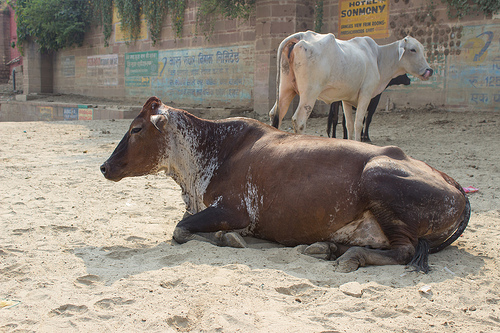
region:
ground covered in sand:
[221, 297, 277, 331]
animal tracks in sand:
[24, 247, 181, 330]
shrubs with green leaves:
[7, 2, 91, 57]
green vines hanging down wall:
[92, 2, 255, 45]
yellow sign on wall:
[333, 0, 400, 40]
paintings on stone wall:
[53, 41, 255, 107]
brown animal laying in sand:
[80, 90, 461, 292]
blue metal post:
[7, 66, 21, 97]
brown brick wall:
[257, 7, 299, 32]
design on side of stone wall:
[464, 23, 498, 70]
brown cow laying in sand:
[100, 98, 473, 292]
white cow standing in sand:
[268, 28, 434, 141]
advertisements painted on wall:
[53, 51, 258, 106]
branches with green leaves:
[8, 3, 267, 54]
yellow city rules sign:
[336, 1, 395, 45]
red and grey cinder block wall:
[5, 6, 498, 123]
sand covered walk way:
[3, 111, 499, 332]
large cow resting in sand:
[94, 93, 473, 283]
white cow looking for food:
[271, 26, 446, 142]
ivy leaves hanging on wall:
[13, 3, 283, 50]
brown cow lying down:
[97, 95, 471, 278]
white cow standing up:
[265, 25, 434, 144]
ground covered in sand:
[0, 116, 497, 331]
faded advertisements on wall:
[48, 0, 498, 111]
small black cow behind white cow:
[326, 72, 410, 144]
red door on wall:
[4, 8, 21, 80]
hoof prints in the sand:
[26, 220, 194, 331]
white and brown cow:
[100, 92, 475, 277]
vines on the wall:
[7, 0, 249, 51]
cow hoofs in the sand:
[218, 226, 367, 273]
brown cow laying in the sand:
[97, 80, 469, 285]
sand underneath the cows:
[6, 179, 99, 329]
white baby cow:
[266, 5, 433, 128]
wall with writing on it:
[69, 36, 270, 96]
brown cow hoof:
[218, 230, 246, 248]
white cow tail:
[267, 32, 309, 133]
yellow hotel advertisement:
[337, 0, 392, 37]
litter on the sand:
[462, 180, 479, 195]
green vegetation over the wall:
[4, 0, 103, 53]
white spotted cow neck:
[147, 109, 237, 223]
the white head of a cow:
[389, 31, 443, 85]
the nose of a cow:
[416, 64, 441, 81]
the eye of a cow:
[406, 41, 420, 57]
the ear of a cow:
[395, 36, 412, 61]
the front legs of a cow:
[337, 96, 374, 139]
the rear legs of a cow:
[263, 85, 321, 133]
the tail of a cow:
[404, 169, 475, 274]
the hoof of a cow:
[327, 254, 365, 275]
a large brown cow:
[81, 91, 478, 280]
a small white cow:
[263, 28, 435, 142]